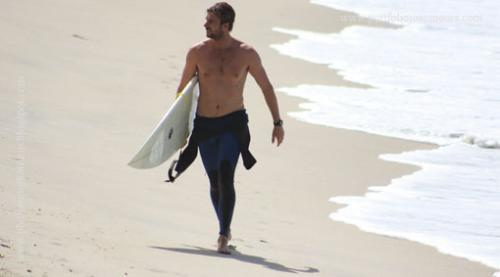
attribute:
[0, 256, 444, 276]
sand — tan, smooth, brown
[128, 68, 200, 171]
surfboard — white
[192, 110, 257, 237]
wetsuit — black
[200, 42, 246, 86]
chest — bare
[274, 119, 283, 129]
watch — black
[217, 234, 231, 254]
feet — bare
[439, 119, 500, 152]
waves — white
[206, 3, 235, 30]
hair — brown